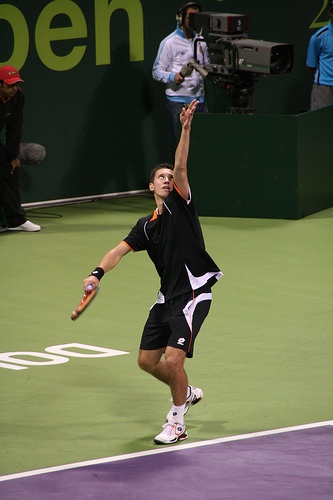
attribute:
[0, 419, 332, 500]
court portion — purple, color purple, purple color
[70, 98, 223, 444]
man — playing tennis, tennis player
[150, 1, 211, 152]
man — filming, camera man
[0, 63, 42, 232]
man — clothed black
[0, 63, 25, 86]
cap — red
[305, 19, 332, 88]
shirt — blue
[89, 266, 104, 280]
wristband — black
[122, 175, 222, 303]
shirt — black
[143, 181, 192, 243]
lines — white, orange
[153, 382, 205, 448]
shoes — white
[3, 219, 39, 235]
shoes — white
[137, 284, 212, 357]
shorts — black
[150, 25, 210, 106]
jacket — white, blue